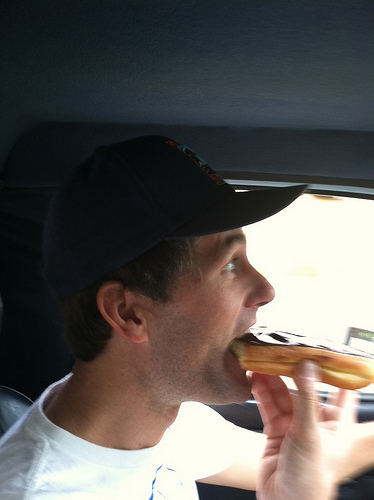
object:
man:
[0, 131, 374, 500]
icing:
[235, 323, 372, 357]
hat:
[39, 134, 309, 304]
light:
[239, 190, 374, 349]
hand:
[247, 358, 360, 500]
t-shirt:
[0, 370, 235, 500]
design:
[148, 459, 185, 500]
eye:
[219, 253, 239, 277]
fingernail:
[298, 360, 314, 379]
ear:
[96, 282, 154, 345]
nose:
[243, 261, 276, 310]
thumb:
[290, 357, 321, 446]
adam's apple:
[163, 401, 181, 431]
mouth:
[226, 320, 258, 372]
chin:
[217, 372, 253, 406]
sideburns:
[135, 255, 180, 302]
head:
[57, 135, 276, 406]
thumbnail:
[299, 362, 315, 378]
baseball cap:
[38, 134, 310, 303]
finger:
[332, 380, 359, 418]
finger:
[250, 368, 280, 425]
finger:
[260, 364, 294, 414]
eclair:
[228, 324, 374, 392]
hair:
[60, 233, 206, 362]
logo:
[164, 138, 228, 188]